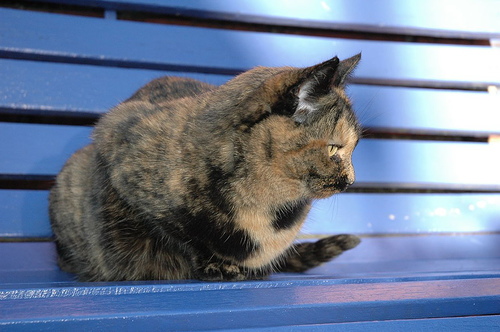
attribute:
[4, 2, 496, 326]
bench — painted, blue, wooden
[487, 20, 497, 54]
bench — wooden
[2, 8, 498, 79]
plank — blue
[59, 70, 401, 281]
cat — black, tan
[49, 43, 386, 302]
cat — down-looking